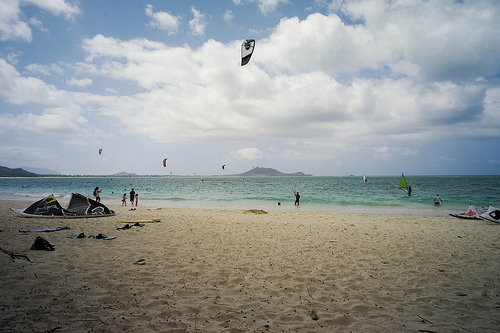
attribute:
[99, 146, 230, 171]
kites — distant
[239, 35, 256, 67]
kite — blue, surfing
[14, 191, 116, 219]
tent — black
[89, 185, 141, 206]
people — group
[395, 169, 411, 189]
sail — yellow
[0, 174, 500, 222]
water — green, large, blue, calm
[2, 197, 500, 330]
beach — white, sandy, brown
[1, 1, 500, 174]
sky — blue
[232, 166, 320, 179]
mountains — distant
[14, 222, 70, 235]
surfboard — blue, green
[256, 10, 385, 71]
cloud — white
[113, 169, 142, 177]
hill — distant